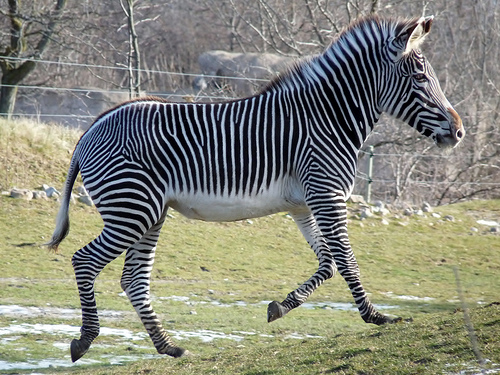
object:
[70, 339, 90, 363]
hoofs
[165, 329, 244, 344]
snow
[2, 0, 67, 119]
tree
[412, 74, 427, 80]
eye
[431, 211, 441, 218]
rocks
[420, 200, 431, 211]
rocks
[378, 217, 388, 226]
rocks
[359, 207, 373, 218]
rocks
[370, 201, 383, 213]
rocks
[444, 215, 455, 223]
rocks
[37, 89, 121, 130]
rock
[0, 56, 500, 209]
fence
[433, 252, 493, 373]
twig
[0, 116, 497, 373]
field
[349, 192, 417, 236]
rocks piled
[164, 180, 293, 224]
belly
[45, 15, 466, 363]
zebra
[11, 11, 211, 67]
bare trees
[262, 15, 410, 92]
mane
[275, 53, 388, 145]
neck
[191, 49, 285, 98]
animal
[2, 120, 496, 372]
pasture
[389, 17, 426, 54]
ear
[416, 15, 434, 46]
ear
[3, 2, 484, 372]
forest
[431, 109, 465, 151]
muzzle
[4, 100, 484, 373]
ground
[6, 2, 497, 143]
background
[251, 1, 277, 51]
tree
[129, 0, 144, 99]
tree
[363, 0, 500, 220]
tree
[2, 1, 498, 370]
park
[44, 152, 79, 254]
tail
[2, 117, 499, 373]
grass